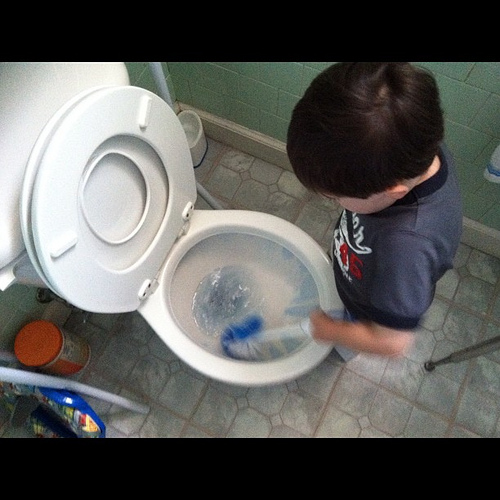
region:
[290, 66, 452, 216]
head of a person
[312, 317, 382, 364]
arm of a person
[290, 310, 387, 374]
an arm of a person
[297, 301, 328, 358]
hand of a person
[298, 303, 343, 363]
a hand of a person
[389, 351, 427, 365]
elbow of a person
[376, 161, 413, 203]
ear of a person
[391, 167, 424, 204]
an ear of a person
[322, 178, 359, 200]
eyebrow of a person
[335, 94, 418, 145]
hair of a person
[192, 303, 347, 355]
this is a toilet brush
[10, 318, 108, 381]
this is a tub of wet wipes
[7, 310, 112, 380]
there is an orange lid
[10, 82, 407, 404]
this is a toilet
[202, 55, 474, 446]
a kid is scrubbing the toilet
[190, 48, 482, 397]
he is scrubbing a toilet bowl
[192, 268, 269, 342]
there is soap in the toilet water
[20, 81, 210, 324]
this is the toilet seat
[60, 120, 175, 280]
there is a potty training seat on the regular seat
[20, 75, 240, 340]
the seat and cover are lifted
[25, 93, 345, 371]
a white toilet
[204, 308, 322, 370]
a toilet brush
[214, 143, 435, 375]
a kid holding a toilet brush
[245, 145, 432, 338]
a kid cleaning the toilet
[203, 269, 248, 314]
water in the toilet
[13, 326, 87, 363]
an orange container on the floor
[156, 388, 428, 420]
white tile on the floor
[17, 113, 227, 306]
a white toilet seat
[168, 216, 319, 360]
the bowl of the toilet seat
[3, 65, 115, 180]
the tank of the toilet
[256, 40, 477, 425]
this is a boy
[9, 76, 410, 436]
this is a toilet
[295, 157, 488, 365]
boy wearing a blue shirt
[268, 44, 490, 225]
boy with brown hair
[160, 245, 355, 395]
this is a toilet brush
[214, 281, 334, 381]
blue and white brush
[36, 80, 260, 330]
toilet seat is up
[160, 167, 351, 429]
brush in the toilet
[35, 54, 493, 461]
boy cleaning the toilet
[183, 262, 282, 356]
suds in the water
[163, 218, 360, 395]
this is a toilet bowl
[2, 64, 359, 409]
the toilet is being cleaned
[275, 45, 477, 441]
this boy is cleaning the bowl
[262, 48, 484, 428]
this boy is cleaning the toilet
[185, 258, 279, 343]
the water has a blue tint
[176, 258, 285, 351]
the blue tint and bubbles are from soap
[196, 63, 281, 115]
there are green tiles on the wall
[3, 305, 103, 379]
this canister has an orange lid